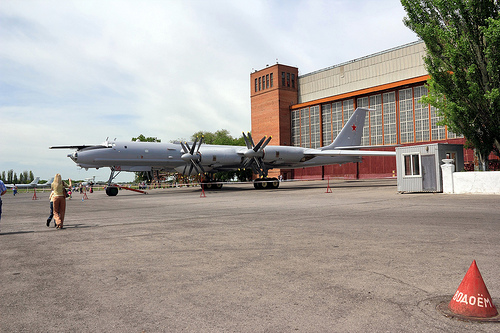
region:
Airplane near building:
[58, 108, 390, 182]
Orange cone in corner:
[445, 253, 497, 330]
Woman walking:
[48, 171, 70, 233]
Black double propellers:
[173, 137, 209, 183]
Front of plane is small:
[62, 132, 172, 173]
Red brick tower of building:
[243, 62, 301, 177]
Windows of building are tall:
[292, 101, 454, 135]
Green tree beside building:
[409, 10, 498, 162]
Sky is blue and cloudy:
[21, 10, 266, 142]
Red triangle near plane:
[320, 168, 340, 198]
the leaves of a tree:
[450, 47, 485, 90]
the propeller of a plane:
[176, 143, 205, 176]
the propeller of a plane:
[237, 133, 276, 175]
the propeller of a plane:
[262, 146, 303, 166]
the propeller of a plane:
[203, 145, 241, 162]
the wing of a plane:
[306, 147, 396, 160]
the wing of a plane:
[6, 182, 36, 189]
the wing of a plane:
[46, 143, 78, 151]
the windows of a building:
[378, 101, 415, 133]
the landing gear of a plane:
[101, 173, 127, 201]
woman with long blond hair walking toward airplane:
[47, 169, 67, 226]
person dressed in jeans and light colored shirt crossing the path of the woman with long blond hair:
[44, 187, 53, 224]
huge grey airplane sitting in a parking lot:
[46, 102, 398, 179]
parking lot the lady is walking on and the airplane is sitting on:
[15, 190, 488, 314]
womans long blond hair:
[49, 172, 63, 190]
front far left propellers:
[237, 125, 267, 172]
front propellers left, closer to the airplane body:
[165, 129, 205, 176]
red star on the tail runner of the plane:
[347, 122, 360, 130]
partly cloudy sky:
[28, 86, 188, 126]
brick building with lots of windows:
[249, 82, 393, 161]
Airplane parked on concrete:
[62, 122, 429, 208]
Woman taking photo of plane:
[47, 166, 87, 254]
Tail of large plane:
[317, 66, 405, 203]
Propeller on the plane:
[171, 135, 213, 180]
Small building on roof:
[382, 140, 486, 215]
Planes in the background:
[7, 167, 51, 201]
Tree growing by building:
[402, 2, 496, 146]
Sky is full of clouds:
[13, 8, 229, 130]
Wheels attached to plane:
[245, 173, 293, 193]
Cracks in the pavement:
[265, 230, 465, 307]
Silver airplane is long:
[61, 106, 397, 198]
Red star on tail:
[348, 120, 359, 132]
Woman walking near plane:
[31, 158, 86, 244]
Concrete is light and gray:
[84, 206, 455, 331]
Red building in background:
[236, 63, 478, 168]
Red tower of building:
[248, 56, 303, 176]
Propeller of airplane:
[180, 130, 207, 174]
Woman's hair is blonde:
[49, 168, 61, 194]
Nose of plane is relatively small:
[70, 123, 140, 169]